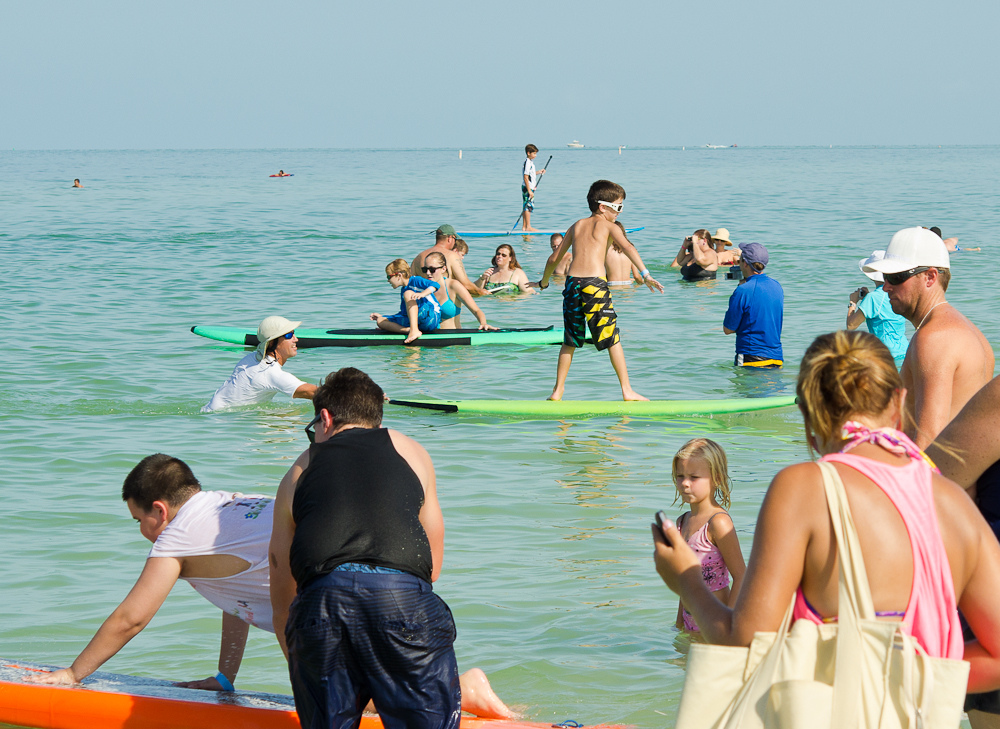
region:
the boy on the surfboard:
[380, 179, 800, 414]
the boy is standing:
[524, 176, 664, 404]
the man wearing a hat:
[198, 309, 316, 427]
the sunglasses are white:
[590, 199, 625, 214]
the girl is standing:
[665, 440, 745, 632]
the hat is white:
[858, 223, 949, 275]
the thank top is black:
[290, 423, 431, 585]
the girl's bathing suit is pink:
[665, 437, 747, 635]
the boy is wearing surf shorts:
[527, 177, 667, 401]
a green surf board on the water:
[375, 382, 810, 414]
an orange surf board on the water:
[0, 658, 638, 726]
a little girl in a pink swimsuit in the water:
[665, 436, 753, 627]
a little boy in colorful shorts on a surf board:
[532, 176, 659, 403]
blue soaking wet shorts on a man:
[282, 561, 464, 726]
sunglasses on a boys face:
[595, 196, 620, 210]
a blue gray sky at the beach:
[2, 0, 996, 165]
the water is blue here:
[168, 156, 376, 278]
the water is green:
[448, 522, 642, 727]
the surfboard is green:
[408, 339, 865, 459]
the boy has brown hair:
[545, 164, 659, 224]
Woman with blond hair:
[795, 329, 897, 459]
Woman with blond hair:
[421, 250, 453, 282]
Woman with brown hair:
[490, 243, 521, 270]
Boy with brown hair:
[584, 177, 625, 215]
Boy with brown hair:
[518, 143, 540, 160]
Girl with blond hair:
[670, 436, 730, 511]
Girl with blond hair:
[381, 256, 413, 291]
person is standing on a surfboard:
[445, 148, 583, 243]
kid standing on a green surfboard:
[382, 187, 819, 439]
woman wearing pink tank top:
[735, 332, 995, 726]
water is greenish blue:
[8, 141, 998, 725]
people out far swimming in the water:
[60, 154, 295, 202]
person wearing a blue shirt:
[724, 239, 789, 387]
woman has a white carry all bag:
[667, 458, 998, 716]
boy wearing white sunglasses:
[550, 178, 648, 415]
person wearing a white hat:
[865, 225, 992, 483]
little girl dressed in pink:
[644, 444, 745, 661]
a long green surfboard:
[374, 396, 815, 417]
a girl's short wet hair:
[668, 426, 742, 508]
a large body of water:
[1, 130, 996, 727]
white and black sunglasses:
[592, 200, 627, 212]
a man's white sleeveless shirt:
[147, 489, 298, 630]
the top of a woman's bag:
[675, 453, 975, 725]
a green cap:
[432, 224, 450, 236]